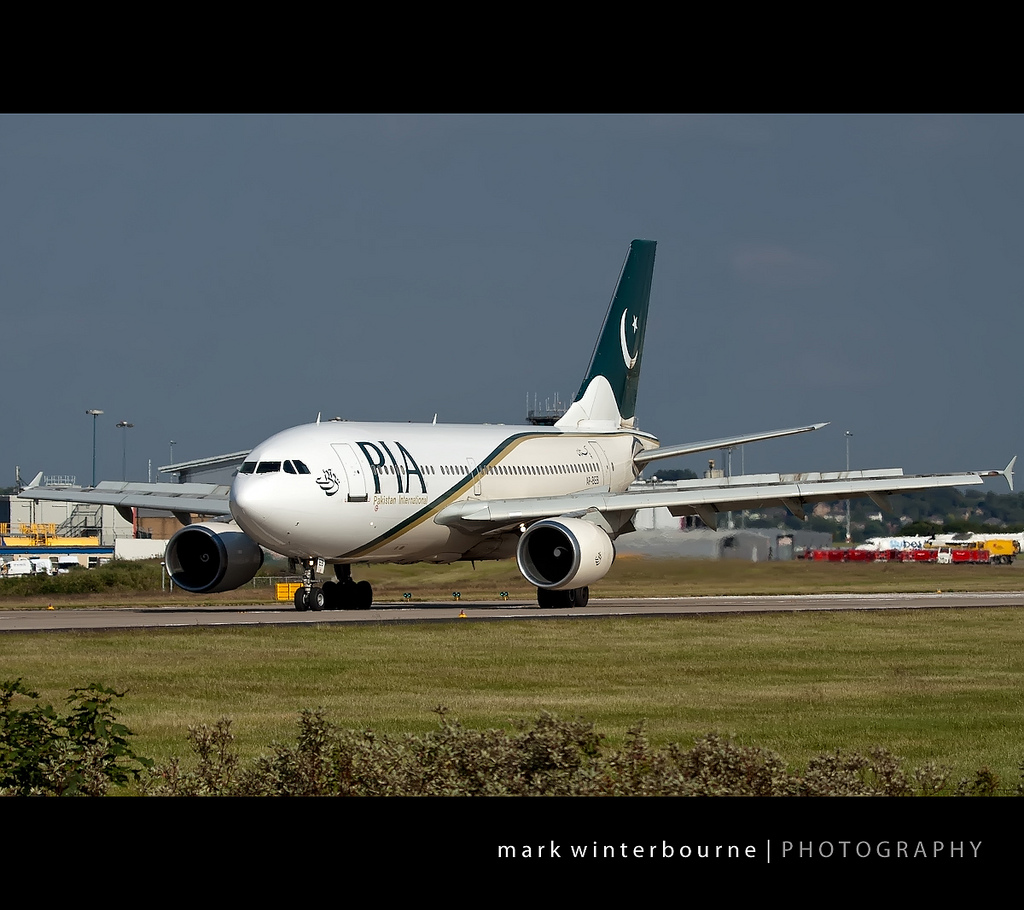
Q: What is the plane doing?
A: Taking off.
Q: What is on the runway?
A: Airplane.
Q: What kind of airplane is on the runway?
A: PIA.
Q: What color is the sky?
A: Grey.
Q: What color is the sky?
A: Grey.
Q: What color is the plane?
A: White.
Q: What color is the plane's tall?
A: Dark green.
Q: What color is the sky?
A: Blue.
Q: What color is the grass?
A: Green.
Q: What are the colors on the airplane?
A: Green and yellow.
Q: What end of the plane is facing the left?
A: Front.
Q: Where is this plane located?
A: Airport runway.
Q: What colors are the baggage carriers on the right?
A: Red and yellow.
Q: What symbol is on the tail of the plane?
A: Crescent moon and star.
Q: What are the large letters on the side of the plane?
A: PIA.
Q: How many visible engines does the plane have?
A: Two.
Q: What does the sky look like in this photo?
A: Dark grey and overcast.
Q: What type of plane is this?
A: Passenger plane.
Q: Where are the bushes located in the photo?
A: Foreground.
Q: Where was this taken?
A: Airport.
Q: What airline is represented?
A: PIA.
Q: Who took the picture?
A: Mark Winterbourne.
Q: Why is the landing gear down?
A: Plane is not flying.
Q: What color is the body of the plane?
A: White.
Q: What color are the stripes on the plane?
A: Yellow and green.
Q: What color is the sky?
A: Blue.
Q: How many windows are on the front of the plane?
A: 4.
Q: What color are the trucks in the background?
A: Red and yellow.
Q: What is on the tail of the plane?
A: Moon and star.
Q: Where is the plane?
A: On the runway.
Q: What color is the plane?
A: White.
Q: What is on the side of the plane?
A: Grass.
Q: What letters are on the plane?
A: PIA.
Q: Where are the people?
A: On the plane.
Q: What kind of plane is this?
A: A passenger plane.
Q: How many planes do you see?
A: 1.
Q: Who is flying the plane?
A: A pilot.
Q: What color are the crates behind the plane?
A: Red.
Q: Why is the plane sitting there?
A: Waiting to take off.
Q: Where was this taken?
A: Airport.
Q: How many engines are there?
A: 2.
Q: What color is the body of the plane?
A: White.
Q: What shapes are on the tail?
A: Moon and star.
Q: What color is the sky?
A: Blue.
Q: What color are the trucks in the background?
A: Yellow and red.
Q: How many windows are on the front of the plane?
A: 4.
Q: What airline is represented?
A: PIA.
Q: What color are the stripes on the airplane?
A: Green and yellow.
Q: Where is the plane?
A: On the runway.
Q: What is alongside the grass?
A: Bushes.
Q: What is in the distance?
A: Buildings.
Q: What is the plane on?
A: Runway.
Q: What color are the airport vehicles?
A: Red and Yellow.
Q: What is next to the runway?
A: Grassy field.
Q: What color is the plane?
A: White.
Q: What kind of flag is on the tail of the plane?
A: Pakistan.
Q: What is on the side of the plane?
A: Windows and doors.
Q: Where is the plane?
A: Runway.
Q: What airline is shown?
A: Pia.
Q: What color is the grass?
A: Green.